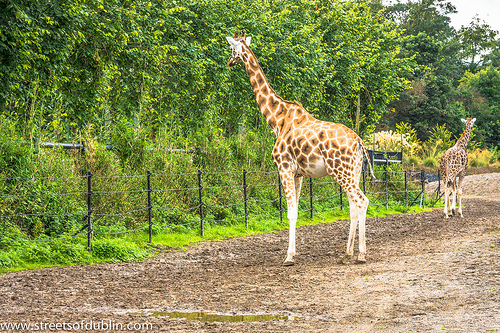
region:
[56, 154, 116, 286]
Black wooden fence post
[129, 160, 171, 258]
Black wooden fence post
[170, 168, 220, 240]
Black wooden fence post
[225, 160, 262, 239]
Black wooden fence post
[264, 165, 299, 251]
Black wooden fence post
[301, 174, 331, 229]
Black wooden fence post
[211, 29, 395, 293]
Tall giraffe standing in the mud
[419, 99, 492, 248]
Tall giraffe standing in the mud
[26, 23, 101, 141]
Green leaves on the tree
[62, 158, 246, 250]
A long fence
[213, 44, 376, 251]
tall giraffe on dirt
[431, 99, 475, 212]
tall giraffe on dirt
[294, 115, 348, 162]
brown and white spots on giraffe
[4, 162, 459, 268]
wire fence in front of giraffes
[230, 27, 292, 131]
long neck on giraffe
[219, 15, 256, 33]
small horns on giraffe's head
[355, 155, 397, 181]
tail hanging on back of giraffe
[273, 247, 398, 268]
giraffe's hoofs in dirt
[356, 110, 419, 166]
thick green bushes in background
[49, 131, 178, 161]
metal pole in woods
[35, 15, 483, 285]
two animals explore their pen area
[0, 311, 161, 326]
website of organization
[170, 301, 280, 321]
small puddle of water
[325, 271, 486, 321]
dirt road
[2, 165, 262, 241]
wire containment fence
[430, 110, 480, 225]
giraffe moving away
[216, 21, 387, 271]
giraffe looking into the woods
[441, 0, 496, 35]
small patch of sky through the trees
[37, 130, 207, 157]
service pipe running through the area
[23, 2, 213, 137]
thick foliage of the woods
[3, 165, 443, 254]
Low Rised Electric Fence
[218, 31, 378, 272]
Adult Giraffe looking into the trees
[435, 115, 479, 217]
Baby Giraffe walking down the trail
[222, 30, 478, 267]
Two Capitive Giraffes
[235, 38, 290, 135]
Giraffe's Long Extended Neck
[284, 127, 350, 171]
Giraffe's unique brown spots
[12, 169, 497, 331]
Long Dirt Trail Along the fence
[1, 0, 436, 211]
Mass amount of vegation on the other side of the fence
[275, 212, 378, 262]
Giraffe's legs are white from the knee down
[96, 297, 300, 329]
Large Water Puddle on the dirt trail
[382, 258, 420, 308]
part of a ground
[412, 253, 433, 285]
part of a ground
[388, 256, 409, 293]
part of a ground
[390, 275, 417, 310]
part of a ground